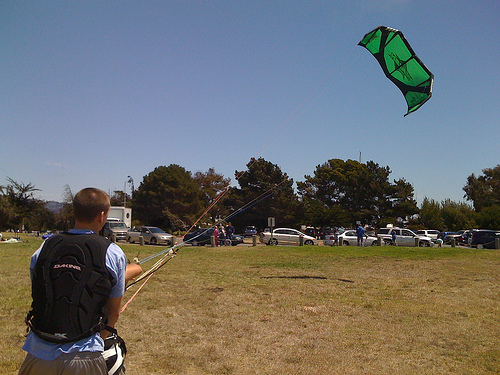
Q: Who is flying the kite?
A: A person.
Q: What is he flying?
A: A kite.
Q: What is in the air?
A: Kite.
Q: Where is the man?
A: On the ground.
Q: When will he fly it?
A: Now.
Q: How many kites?
A: 1.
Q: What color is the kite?
A: Green.